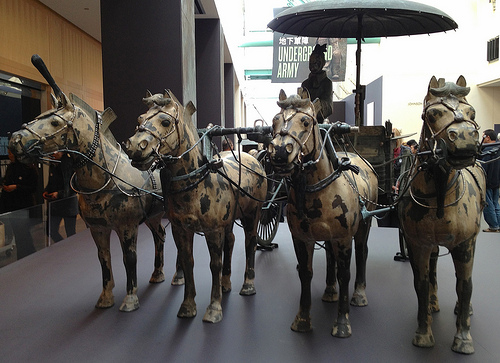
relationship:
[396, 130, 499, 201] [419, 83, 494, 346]
people behind statue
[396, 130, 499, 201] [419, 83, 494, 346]
people right of statue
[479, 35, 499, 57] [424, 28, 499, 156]
vent on wall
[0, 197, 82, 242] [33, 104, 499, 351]
shield for display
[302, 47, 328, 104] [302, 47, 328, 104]
man of man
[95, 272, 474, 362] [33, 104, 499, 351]
hooves on display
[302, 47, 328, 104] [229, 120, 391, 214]
man on carriage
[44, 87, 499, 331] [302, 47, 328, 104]
horses and man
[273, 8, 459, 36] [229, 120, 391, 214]
umbrella over carriage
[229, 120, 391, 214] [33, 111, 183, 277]
carriage of horse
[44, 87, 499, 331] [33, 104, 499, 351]
horses on display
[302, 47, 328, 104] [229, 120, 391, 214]
man in carriage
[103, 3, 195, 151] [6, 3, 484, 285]
pillar in room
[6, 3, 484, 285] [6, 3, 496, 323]
room of museum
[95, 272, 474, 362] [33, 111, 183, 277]
hooves of horse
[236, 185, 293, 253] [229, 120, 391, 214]
wheel of carriage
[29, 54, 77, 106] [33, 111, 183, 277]
halter of horse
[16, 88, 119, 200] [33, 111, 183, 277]
headshot of horse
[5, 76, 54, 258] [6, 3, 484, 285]
entrance in room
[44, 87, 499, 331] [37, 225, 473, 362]
horses on table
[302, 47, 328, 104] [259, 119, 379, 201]
man of chariot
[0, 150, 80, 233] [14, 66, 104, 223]
pedestrians in hallway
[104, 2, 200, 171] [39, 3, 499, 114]
column supports roof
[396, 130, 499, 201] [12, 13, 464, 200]
people in background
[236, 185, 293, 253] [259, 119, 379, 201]
wheel of chariot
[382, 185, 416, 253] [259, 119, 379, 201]
wheel of chariot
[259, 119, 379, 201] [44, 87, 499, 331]
chariot hitched to horses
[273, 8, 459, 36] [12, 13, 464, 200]
umbrella in background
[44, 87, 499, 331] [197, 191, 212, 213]
horses have black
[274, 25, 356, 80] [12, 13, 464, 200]
sign in background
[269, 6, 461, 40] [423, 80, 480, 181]
black above head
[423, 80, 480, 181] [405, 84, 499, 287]
head of horse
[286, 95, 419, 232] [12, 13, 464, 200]
wagon in background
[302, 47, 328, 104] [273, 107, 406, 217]
man in wagon